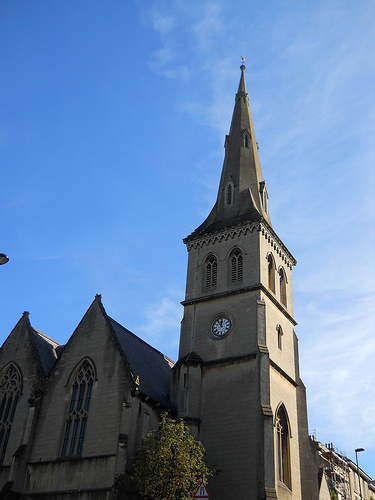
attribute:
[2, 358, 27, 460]
window — detailed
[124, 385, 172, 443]
detail — attractive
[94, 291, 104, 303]
detail — attractive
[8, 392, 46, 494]
detail — attractive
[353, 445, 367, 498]
light — street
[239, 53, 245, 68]
vane — weather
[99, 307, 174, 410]
roof — high, pitched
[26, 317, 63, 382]
roof — high, pitched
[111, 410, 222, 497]
tree — half-way, dying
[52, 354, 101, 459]
window — detailed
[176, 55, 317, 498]
steeple — tall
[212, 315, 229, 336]
face — white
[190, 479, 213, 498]
sign — red, black, white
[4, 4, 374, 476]
sky — blue, bright blue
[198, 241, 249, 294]
windows — identical 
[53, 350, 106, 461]
window — fancy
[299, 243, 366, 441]
cloud — big